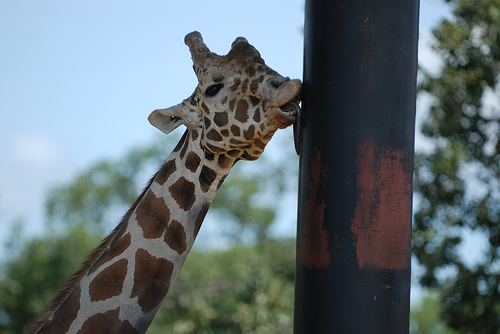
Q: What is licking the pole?
A: A giraffe.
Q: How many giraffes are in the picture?
A: One.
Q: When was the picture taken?
A: During the day.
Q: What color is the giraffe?
A: Brown and cream.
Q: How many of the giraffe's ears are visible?
A: One.